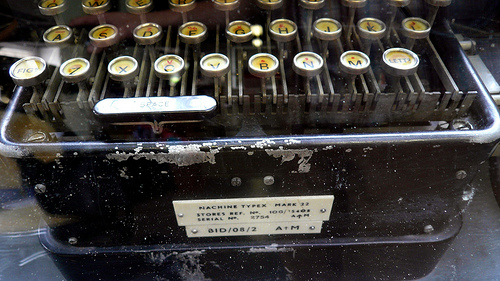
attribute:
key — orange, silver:
[11, 2, 466, 110]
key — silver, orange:
[60, 57, 87, 73]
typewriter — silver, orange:
[7, 21, 460, 122]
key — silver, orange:
[380, 45, 420, 80]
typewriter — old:
[2, 2, 497, 249]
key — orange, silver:
[375, 47, 435, 86]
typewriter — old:
[147, 49, 184, 86]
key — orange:
[339, 47, 374, 69]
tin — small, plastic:
[380, 45, 420, 77]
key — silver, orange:
[295, 53, 320, 74]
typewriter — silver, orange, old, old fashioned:
[8, 7, 499, 279]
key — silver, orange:
[5, 51, 50, 86]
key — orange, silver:
[246, 53, 278, 74]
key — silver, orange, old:
[339, 49, 371, 70]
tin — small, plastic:
[7, 50, 54, 91]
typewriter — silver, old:
[13, 12, 498, 207]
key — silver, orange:
[381, 40, 423, 73]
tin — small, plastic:
[227, 19, 255, 41]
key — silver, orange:
[248, 54, 279, 76]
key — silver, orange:
[42, 25, 72, 45]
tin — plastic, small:
[34, 74, 455, 265]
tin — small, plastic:
[54, 52, 152, 122]